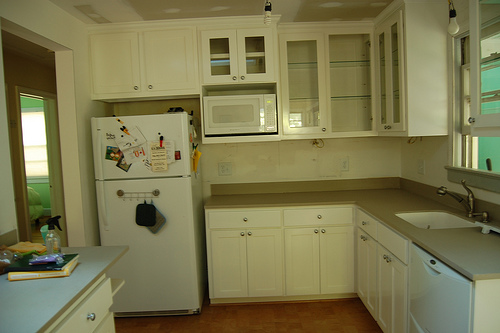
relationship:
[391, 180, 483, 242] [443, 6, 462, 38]
sink near light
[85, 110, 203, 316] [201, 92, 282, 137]
fridge beside microwave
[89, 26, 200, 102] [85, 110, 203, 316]
cabinets above fridge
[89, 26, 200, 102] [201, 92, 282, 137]
cabinets above microwave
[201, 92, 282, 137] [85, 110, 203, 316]
microwave by fridge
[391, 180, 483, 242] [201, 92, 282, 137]
sink near microwave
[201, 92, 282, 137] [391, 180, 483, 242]
microwave near sink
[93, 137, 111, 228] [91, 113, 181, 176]
handle on freezer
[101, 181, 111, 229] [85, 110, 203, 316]
handle on fridge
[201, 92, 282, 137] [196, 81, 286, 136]
microwave in cubby